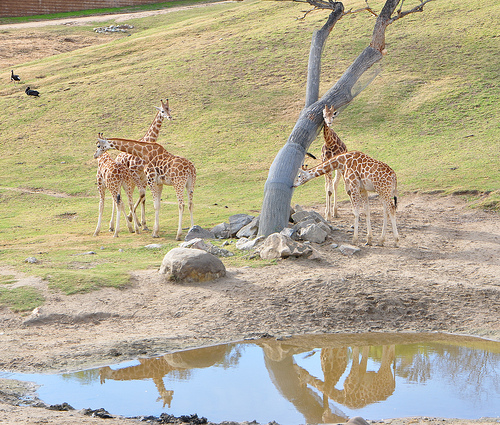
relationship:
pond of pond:
[0, 329, 500, 425] [0, 329, 500, 425]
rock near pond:
[149, 235, 238, 286] [142, 302, 301, 387]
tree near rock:
[228, 56, 367, 221] [149, 235, 238, 286]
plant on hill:
[83, 14, 129, 49] [401, 11, 467, 93]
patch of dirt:
[433, 228, 478, 274] [436, 203, 453, 224]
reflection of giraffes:
[330, 344, 409, 409] [316, 103, 351, 221]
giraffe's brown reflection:
[100, 139, 203, 218] [330, 344, 409, 409]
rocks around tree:
[240, 222, 300, 282] [228, 56, 367, 221]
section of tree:
[272, 136, 305, 191] [228, 56, 367, 221]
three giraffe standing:
[57, 74, 218, 231] [147, 147, 188, 239]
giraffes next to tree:
[316, 103, 351, 221] [228, 56, 367, 221]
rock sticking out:
[149, 235, 238, 286] [192, 219, 218, 268]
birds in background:
[20, 73, 48, 112] [27, 45, 43, 77]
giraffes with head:
[316, 103, 351, 221] [288, 163, 313, 209]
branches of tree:
[371, 2, 440, 35] [228, 56, 367, 221]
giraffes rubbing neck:
[316, 103, 351, 221] [316, 150, 342, 180]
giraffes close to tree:
[294, 103, 364, 161] [228, 56, 367, 221]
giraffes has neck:
[316, 103, 351, 221] [316, 150, 342, 180]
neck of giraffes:
[316, 150, 342, 180] [316, 103, 351, 221]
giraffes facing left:
[316, 103, 351, 221] [7, 127, 39, 173]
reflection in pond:
[291, 344, 399, 424] [0, 329, 500, 425]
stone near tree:
[272, 188, 326, 273] [228, 56, 367, 221]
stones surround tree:
[275, 209, 326, 245] [228, 56, 367, 221]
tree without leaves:
[228, 56, 367, 221] [371, 2, 440, 35]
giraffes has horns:
[316, 103, 351, 221] [153, 90, 173, 110]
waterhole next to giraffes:
[299, 331, 469, 402] [294, 103, 364, 161]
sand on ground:
[269, 273, 307, 309] [344, 210, 438, 298]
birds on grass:
[20, 73, 48, 112] [19, 115, 49, 141]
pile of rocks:
[280, 206, 313, 267] [240, 222, 300, 282]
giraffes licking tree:
[316, 103, 351, 221] [228, 56, 367, 221]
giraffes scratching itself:
[316, 103, 351, 221] [241, 129, 360, 158]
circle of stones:
[207, 208, 325, 275] [275, 209, 326, 245]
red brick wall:
[39, 8, 63, 22] [13, 4, 58, 25]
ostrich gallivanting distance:
[1, 64, 34, 91] [27, 58, 38, 71]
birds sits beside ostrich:
[22, 86, 40, 100] [1, 64, 34, 91]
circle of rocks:
[207, 208, 325, 275] [240, 222, 300, 282]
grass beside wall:
[19, 115, 49, 141] [13, 4, 58, 25]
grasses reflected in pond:
[398, 348, 425, 360] [142, 302, 301, 387]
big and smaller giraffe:
[145, 71, 193, 165] [86, 150, 128, 230]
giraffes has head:
[316, 103, 351, 221] [288, 163, 313, 209]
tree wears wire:
[228, 56, 367, 221] [328, 59, 394, 97]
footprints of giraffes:
[293, 275, 330, 305] [316, 103, 351, 221]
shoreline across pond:
[209, 313, 368, 351] [61, 352, 464, 422]